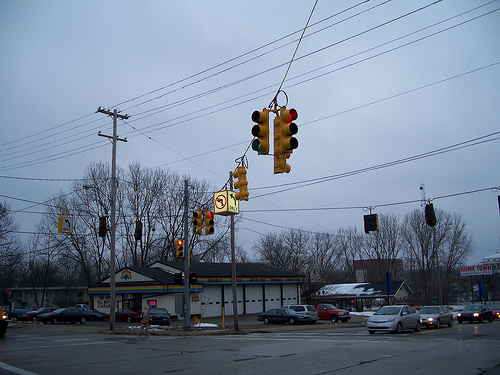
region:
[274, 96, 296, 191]
yellow traffic light showing red.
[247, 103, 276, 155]
yellow traffic light showing green.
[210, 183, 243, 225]
white one way sign with red outline.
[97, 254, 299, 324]
white yellow and blue building.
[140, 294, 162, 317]
red open sign on business.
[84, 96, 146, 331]
telephone pole on road side.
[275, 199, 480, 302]
trees with no leaves and street signs.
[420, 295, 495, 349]
two cars with head lights on.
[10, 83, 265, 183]
telephone wires in air.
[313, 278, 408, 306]
snow on roof of building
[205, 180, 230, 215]
no left turn sign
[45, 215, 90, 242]
turn left lane sign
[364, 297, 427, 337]
silver compact car at red light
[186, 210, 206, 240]
green light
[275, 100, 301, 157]
red light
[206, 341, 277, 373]
water puddled in the middle of the road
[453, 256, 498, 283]
sign that says Home Town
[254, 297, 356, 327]
multiple cars parked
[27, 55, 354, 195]
very dark looking sky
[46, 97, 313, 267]
the traffic lights are yellow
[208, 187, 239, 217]
one light has an arrow on it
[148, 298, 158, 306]
open sign in window of store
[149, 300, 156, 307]
open sign is red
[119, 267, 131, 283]
rainbow colored logo over door on building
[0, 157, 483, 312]
the trees have no leaves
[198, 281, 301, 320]
the building has 4 garage doors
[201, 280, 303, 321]
the garage doors are all closed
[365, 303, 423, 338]
the car in the front of the line is silver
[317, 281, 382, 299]
there is snow on the black roof of the building in the back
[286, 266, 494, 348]
cars are stopped on the street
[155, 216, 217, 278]
the traffic light is glowing red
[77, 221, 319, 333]
the garage has five doors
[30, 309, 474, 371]
the road is wet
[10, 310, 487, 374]
the road is grey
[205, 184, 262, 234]
the turning sign is bright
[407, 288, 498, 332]
cars have their headlights on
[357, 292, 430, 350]
the car in front is silver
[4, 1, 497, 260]
power lines hang above cars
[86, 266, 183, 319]
the sign on the building is pink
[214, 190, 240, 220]
traffic signs for traffic.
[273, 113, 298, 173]
traffic lights for the cars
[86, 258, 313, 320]
a building for people to go to.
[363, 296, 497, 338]
a row of traffic on the street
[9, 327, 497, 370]
the intersection of the street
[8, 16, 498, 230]
power lines above the cars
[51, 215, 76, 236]
a no left turn traffic sign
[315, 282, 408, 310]
a house with snow on the roof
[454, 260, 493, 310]
a sign for the store.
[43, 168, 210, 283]
a big tree with no leaves